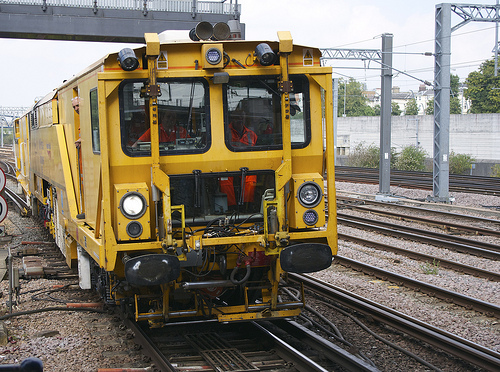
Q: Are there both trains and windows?
A: Yes, there are both a window and a train.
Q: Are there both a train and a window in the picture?
A: Yes, there are both a window and a train.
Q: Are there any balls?
A: No, there are no balls.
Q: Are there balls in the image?
A: No, there are no balls.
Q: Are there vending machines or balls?
A: No, there are no balls or vending machines.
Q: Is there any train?
A: Yes, there is a train.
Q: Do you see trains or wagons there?
A: Yes, there is a train.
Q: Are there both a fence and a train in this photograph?
A: No, there is a train but no fences.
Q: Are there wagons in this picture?
A: No, there are no wagons.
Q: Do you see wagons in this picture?
A: No, there are no wagons.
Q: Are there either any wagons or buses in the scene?
A: No, there are no wagons or buses.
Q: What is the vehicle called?
A: The vehicle is a train.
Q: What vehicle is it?
A: The vehicle is a train.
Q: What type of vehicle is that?
A: This is a train.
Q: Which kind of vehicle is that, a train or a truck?
A: This is a train.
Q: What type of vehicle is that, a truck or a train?
A: This is a train.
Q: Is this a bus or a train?
A: This is a train.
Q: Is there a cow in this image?
A: No, there are no cows.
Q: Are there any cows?
A: No, there are no cows.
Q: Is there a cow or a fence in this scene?
A: No, there are no cows or fences.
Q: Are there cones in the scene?
A: No, there are no cones.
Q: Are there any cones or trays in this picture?
A: No, there are no cones or trays.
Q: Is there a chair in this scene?
A: No, there are no chairs.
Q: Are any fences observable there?
A: No, there are no fences.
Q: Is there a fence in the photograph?
A: No, there are no fences.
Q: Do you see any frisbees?
A: No, there are no frisbees.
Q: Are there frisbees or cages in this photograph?
A: No, there are no frisbees or cages.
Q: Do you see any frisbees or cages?
A: No, there are no frisbees or cages.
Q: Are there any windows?
A: Yes, there is a window.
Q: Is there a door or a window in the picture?
A: Yes, there is a window.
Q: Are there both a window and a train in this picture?
A: Yes, there are both a window and a train.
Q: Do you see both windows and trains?
A: Yes, there are both a window and a train.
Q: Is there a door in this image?
A: No, there are no doors.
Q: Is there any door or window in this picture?
A: Yes, there is a window.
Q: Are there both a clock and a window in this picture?
A: No, there is a window but no clocks.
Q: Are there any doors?
A: No, there are no doors.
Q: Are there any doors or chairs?
A: No, there are no doors or chairs.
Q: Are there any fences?
A: No, there are no fences.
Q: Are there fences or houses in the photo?
A: No, there are no fences or houses.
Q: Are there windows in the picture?
A: Yes, there is a window.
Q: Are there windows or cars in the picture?
A: Yes, there is a window.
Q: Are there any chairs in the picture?
A: No, there are no chairs.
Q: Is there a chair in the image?
A: No, there are no chairs.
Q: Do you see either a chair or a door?
A: No, there are no chairs or doors.